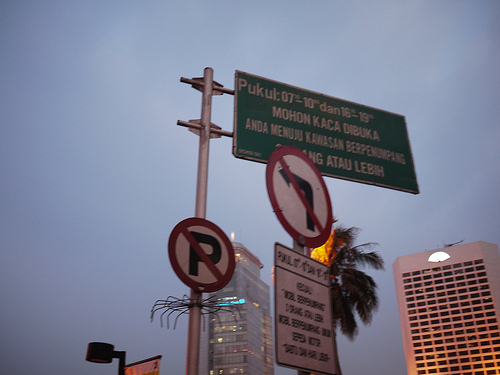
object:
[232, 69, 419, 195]
sign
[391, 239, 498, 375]
building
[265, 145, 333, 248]
sign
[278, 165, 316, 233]
no left turns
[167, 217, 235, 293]
sign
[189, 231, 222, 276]
no parking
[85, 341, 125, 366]
streetlight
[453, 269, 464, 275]
windows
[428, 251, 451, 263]
logo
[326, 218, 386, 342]
palm tree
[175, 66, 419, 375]
signs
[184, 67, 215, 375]
pole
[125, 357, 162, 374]
banner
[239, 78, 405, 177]
white letters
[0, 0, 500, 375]
sky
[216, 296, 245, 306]
light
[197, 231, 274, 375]
building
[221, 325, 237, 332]
windows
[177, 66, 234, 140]
bracket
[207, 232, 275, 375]
lights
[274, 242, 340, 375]
sign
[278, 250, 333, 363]
black writing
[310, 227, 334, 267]
light